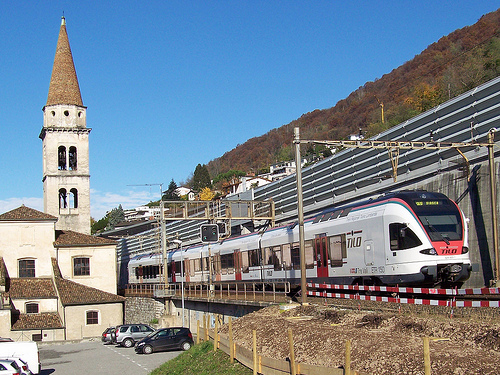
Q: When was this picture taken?
A: Daytime.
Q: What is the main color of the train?
A: White.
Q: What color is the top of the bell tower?
A: Brown.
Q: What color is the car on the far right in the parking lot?
A: Black.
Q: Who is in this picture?
A: No one.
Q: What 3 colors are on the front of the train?
A: Red, white, black.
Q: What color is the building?
A: Cream.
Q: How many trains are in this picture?
A: One.